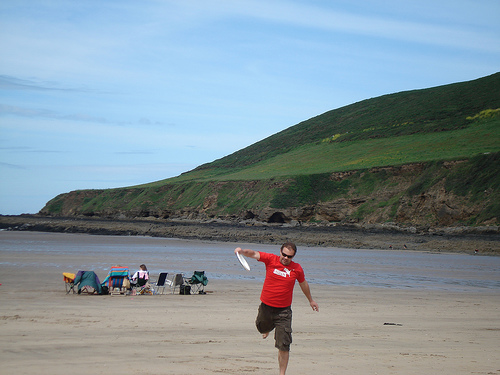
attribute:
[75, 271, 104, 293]
jacket — green, purple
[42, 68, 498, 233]
grassy hill — green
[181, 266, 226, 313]
chairs — grouped, fold up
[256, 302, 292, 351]
shorts — brown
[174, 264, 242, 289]
chair — green , black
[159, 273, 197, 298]
bag — black 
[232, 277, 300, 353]
shorts — olive, cargo short